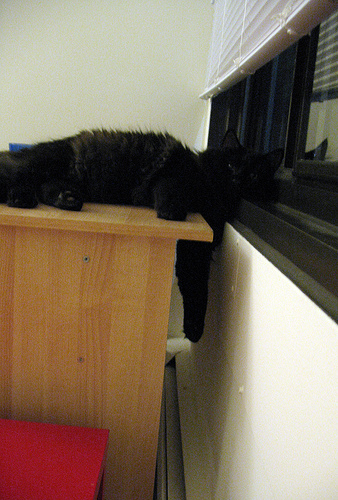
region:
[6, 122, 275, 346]
A black cat lying on a desk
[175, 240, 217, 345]
A dangling black cat's paw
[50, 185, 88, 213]
The back foot of a cat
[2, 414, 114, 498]
A red table top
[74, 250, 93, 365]
Two screws on a desk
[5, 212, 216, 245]
The edge of a desk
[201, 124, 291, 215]
The head of a black cat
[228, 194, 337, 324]
A window sill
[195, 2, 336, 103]
White window blinds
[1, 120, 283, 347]
A fluffy black cat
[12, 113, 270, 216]
black cat laying on desk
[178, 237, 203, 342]
cat's paw hanging off desk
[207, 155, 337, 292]
black window ledge cat's head is on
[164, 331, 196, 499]
white vent on white wall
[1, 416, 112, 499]
red table next to desk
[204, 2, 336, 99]
white blinds partially pulled up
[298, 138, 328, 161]
cat's ear reflected on window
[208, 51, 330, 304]
black framed window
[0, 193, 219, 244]
desktop cat is laying on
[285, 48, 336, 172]
windw and blinds reflected on window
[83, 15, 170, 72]
this is the wall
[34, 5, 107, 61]
the wall is white in color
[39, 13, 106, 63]
the wall is clean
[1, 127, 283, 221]
this is a cat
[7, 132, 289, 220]
the cat is big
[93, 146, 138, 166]
the fur is black in color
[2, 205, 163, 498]
this is a table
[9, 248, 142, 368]
the table is wooden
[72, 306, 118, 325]
the wood is brown in color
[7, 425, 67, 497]
the object is red in color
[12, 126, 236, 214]
black cat sleeping on dresser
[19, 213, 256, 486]
wooden dresser in room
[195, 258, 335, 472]
white wall on right side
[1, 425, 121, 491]
small red table near dresser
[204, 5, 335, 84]
white blinds hanging from window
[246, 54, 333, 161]
glass window on right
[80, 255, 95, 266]
round metal screw in wood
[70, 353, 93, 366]
round metal screw in wood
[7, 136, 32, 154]
blue object on dresser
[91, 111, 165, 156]
long dark fur of cat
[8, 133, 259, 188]
a black scarly cat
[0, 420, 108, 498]
theb red seat o f a chair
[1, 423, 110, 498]
a wooden red chair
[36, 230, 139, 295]
a wooden table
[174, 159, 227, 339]
the cat has its paw stretched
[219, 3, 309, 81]
white windows of the window are open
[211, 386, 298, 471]
white square wall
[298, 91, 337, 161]
a mirror on the wall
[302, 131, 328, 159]
the image of the cat on the mirror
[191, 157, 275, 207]
the cat is awake